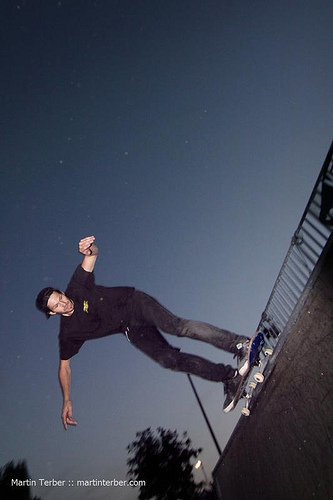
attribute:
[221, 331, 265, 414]
deck — blue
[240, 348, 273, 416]
wheels — white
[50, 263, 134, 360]
shirt — black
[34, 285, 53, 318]
hat — black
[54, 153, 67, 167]
star — glaring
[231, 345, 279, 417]
wheels — white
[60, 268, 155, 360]
shirt — black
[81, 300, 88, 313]
mark — yellow